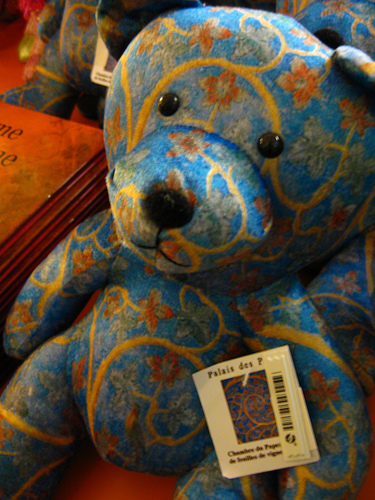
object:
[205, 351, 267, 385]
words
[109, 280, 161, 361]
pattern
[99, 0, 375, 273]
head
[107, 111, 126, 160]
flowers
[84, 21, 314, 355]
print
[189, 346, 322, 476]
tag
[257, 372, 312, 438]
code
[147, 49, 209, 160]
bird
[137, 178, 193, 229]
nose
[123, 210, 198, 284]
mouth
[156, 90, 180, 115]
eye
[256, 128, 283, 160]
eye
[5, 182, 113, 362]
arm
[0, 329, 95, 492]
leg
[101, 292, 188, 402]
belly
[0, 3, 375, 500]
bear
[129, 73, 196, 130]
plastic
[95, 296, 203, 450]
design